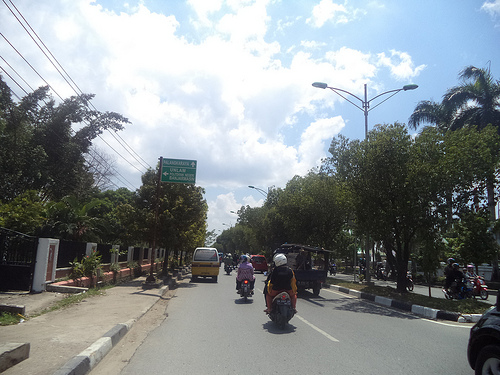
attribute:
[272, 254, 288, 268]
helmet — white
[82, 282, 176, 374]
pavement — missing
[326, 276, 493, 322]
sidewalk — gray, white, black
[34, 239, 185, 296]
retaining wall — red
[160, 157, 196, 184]
sign — green, directional, white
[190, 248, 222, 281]
vehicle — yellow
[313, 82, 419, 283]
streetlamp — metal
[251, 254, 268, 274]
car — red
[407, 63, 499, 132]
foliage — tropical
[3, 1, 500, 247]
sky — blue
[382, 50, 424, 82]
cloud — puffy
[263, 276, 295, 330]
motorcycle — moving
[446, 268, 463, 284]
shirt — black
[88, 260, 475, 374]
road — asphalt, tarmacked, clean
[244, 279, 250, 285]
rear light — on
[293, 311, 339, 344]
strip — white